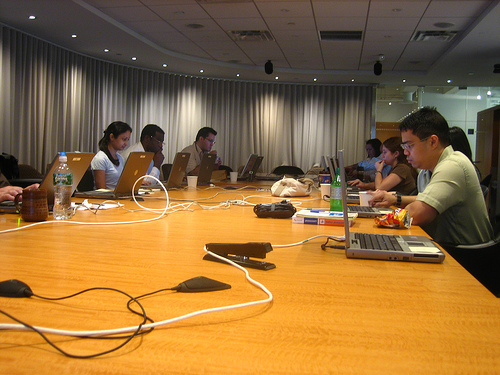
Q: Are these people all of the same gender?
A: No, they are both male and female.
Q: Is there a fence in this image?
A: No, there are no fences.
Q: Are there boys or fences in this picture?
A: No, there are no fences or boys.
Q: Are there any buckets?
A: No, there are no buckets.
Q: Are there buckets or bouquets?
A: No, there are no buckets or bouquets.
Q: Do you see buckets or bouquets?
A: No, there are no buckets or bouquets.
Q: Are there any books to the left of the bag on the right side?
A: Yes, there is a book to the left of the bag.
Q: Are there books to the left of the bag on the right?
A: Yes, there is a book to the left of the bag.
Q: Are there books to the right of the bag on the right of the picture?
A: No, the book is to the left of the bag.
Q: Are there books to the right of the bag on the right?
A: No, the book is to the left of the bag.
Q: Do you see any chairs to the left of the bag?
A: No, there is a book to the left of the bag.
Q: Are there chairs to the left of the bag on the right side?
A: No, there is a book to the left of the bag.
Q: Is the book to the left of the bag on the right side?
A: Yes, the book is to the left of the bag.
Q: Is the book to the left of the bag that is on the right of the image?
A: Yes, the book is to the left of the bag.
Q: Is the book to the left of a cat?
A: No, the book is to the left of the bag.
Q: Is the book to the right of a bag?
A: No, the book is to the left of a bag.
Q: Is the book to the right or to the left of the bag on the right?
A: The book is to the left of the bag.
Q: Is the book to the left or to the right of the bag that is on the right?
A: The book is to the left of the bag.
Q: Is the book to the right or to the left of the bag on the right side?
A: The book is to the left of the bag.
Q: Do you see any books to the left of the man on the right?
A: Yes, there is a book to the left of the man.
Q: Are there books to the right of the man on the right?
A: No, the book is to the left of the man.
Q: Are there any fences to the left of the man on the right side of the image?
A: No, there is a book to the left of the man.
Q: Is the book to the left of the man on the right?
A: Yes, the book is to the left of the man.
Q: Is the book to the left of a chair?
A: No, the book is to the left of the man.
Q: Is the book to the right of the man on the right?
A: No, the book is to the left of the man.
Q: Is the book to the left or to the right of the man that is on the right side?
A: The book is to the left of the man.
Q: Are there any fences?
A: No, there are no fences.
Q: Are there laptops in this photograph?
A: Yes, there is a laptop.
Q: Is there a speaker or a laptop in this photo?
A: Yes, there is a laptop.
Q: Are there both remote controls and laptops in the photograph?
A: No, there is a laptop but no remote controls.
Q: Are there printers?
A: No, there are no printers.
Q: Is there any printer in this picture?
A: No, there are no printers.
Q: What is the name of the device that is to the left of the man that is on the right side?
A: The device is a laptop.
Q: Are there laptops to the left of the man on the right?
A: Yes, there is a laptop to the left of the man.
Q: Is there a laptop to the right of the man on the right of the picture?
A: No, the laptop is to the left of the man.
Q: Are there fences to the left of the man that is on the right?
A: No, there is a laptop to the left of the man.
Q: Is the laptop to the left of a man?
A: Yes, the laptop is to the left of a man.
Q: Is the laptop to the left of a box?
A: No, the laptop is to the left of a man.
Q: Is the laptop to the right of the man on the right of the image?
A: No, the laptop is to the left of the man.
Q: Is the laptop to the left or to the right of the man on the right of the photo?
A: The laptop is to the left of the man.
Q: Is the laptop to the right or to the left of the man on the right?
A: The laptop is to the left of the man.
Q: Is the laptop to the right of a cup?
A: Yes, the laptop is to the right of a cup.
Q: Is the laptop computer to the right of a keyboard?
A: No, the laptop computer is to the right of a cup.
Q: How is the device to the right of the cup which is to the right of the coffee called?
A: The device is a laptop.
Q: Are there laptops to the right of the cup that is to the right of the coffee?
A: Yes, there is a laptop to the right of the cup.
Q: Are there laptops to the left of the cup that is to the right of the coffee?
A: No, the laptop is to the right of the cup.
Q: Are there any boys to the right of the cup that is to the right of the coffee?
A: No, there is a laptop to the right of the cup.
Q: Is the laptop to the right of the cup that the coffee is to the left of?
A: Yes, the laptop is to the right of the cup.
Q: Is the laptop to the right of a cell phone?
A: No, the laptop is to the right of the cup.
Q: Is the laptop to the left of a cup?
A: No, the laptop is to the right of a cup.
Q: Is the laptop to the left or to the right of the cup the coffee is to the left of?
A: The laptop is to the right of the cup.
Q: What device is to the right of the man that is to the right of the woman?
A: The device is a laptop.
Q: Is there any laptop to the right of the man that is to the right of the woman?
A: Yes, there is a laptop to the right of the man.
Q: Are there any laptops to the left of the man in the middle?
A: No, the laptop is to the right of the man.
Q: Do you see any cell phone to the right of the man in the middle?
A: No, there is a laptop to the right of the man.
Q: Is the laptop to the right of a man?
A: Yes, the laptop is to the right of a man.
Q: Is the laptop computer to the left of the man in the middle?
A: No, the laptop computer is to the right of the man.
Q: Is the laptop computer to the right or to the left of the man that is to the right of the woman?
A: The laptop computer is to the right of the man.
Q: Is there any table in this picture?
A: Yes, there is a table.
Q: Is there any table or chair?
A: Yes, there is a table.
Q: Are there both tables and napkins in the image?
A: No, there is a table but no napkins.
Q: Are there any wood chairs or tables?
A: Yes, there is a wood table.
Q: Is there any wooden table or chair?
A: Yes, there is a wood table.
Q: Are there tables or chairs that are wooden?
A: Yes, the table is wooden.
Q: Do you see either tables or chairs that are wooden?
A: Yes, the table is wooden.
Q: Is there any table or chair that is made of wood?
A: Yes, the table is made of wood.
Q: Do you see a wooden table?
A: Yes, there is a wood table.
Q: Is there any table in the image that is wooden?
A: Yes, there is a table that is wooden.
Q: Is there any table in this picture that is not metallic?
A: Yes, there is a wooden table.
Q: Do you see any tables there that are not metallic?
A: Yes, there is a wooden table.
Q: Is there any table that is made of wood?
A: Yes, there is a table that is made of wood.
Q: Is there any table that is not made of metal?
A: Yes, there is a table that is made of wood.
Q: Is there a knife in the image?
A: No, there are no knives.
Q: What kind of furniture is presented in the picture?
A: The furniture is a table.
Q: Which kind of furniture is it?
A: The piece of furniture is a table.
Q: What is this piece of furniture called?
A: This is a table.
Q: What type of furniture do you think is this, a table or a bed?
A: This is a table.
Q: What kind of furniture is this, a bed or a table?
A: This is a table.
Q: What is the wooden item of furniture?
A: The piece of furniture is a table.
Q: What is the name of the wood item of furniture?
A: The piece of furniture is a table.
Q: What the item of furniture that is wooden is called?
A: The piece of furniture is a table.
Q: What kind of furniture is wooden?
A: The furniture is a table.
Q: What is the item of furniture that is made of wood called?
A: The piece of furniture is a table.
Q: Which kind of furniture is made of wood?
A: The furniture is a table.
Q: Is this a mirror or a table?
A: This is a table.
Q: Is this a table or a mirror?
A: This is a table.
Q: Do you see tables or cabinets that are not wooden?
A: No, there is a table but it is wooden.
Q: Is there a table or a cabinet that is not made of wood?
A: No, there is a table but it is made of wood.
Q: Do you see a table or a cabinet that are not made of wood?
A: No, there is a table but it is made of wood.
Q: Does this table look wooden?
A: Yes, the table is wooden.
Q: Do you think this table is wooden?
A: Yes, the table is wooden.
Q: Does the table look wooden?
A: Yes, the table is wooden.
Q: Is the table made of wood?
A: Yes, the table is made of wood.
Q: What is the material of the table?
A: The table is made of wood.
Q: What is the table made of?
A: The table is made of wood.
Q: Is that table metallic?
A: No, the table is wooden.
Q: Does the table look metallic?
A: No, the table is wooden.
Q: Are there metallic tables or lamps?
A: No, there is a table but it is wooden.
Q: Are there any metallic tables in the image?
A: No, there is a table but it is wooden.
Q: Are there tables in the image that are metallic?
A: No, there is a table but it is wooden.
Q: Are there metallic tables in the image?
A: No, there is a table but it is wooden.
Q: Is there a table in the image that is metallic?
A: No, there is a table but it is wooden.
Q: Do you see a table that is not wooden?
A: No, there is a table but it is wooden.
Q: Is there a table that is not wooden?
A: No, there is a table but it is wooden.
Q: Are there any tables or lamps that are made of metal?
A: No, there is a table but it is made of wood.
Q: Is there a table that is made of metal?
A: No, there is a table but it is made of wood.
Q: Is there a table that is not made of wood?
A: No, there is a table but it is made of wood.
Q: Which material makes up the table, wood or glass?
A: The table is made of wood.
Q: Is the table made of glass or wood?
A: The table is made of wood.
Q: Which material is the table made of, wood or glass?
A: The table is made of wood.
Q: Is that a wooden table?
A: Yes, that is a wooden table.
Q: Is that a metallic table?
A: No, that is a wooden table.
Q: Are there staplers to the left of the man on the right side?
A: Yes, there is a stapler to the left of the man.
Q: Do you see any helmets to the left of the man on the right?
A: No, there is a stapler to the left of the man.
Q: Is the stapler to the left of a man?
A: Yes, the stapler is to the left of a man.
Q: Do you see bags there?
A: Yes, there is a bag.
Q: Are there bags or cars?
A: Yes, there is a bag.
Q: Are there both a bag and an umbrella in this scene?
A: No, there is a bag but no umbrellas.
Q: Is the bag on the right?
A: Yes, the bag is on the right of the image.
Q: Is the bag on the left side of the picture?
A: No, the bag is on the right of the image.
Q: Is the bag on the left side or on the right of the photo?
A: The bag is on the right of the image.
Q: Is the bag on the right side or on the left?
A: The bag is on the right of the image.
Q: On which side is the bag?
A: The bag is on the right of the image.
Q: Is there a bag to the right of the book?
A: Yes, there is a bag to the right of the book.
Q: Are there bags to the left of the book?
A: No, the bag is to the right of the book.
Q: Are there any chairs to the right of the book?
A: No, there is a bag to the right of the book.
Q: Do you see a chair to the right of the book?
A: No, there is a bag to the right of the book.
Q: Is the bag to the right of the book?
A: Yes, the bag is to the right of the book.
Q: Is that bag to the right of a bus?
A: No, the bag is to the right of the book.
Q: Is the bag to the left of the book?
A: No, the bag is to the right of the book.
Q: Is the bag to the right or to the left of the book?
A: The bag is to the right of the book.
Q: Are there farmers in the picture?
A: No, there are no farmers.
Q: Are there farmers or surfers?
A: No, there are no farmers or surfers.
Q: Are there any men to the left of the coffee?
A: Yes, there is a man to the left of the coffee.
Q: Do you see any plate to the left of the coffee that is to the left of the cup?
A: No, there is a man to the left of the coffee.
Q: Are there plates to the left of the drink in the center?
A: No, there is a man to the left of the coffee.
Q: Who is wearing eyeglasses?
A: The man is wearing eyeglasses.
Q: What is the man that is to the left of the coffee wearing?
A: The man is wearing eye glasses.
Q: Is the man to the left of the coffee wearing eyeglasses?
A: Yes, the man is wearing eyeglasses.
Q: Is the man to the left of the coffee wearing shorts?
A: No, the man is wearing eyeglasses.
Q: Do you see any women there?
A: Yes, there is a woman.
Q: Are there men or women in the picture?
A: Yes, there is a woman.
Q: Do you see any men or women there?
A: Yes, there is a woman.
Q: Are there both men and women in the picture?
A: Yes, there are both a woman and a man.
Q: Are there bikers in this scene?
A: No, there are no bikers.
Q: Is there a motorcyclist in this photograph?
A: No, there are no bikers.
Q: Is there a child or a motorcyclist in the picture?
A: No, there are no bikers or children.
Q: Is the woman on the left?
A: Yes, the woman is on the left of the image.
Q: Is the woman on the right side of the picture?
A: No, the woman is on the left of the image.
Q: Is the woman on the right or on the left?
A: The woman is on the left of the image.